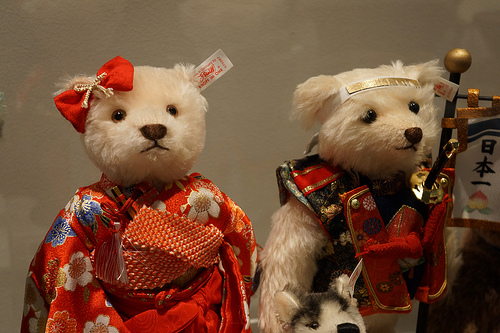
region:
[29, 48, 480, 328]
two teddy bears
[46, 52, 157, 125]
a red bow on the bears ear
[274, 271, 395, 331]
a toy wolf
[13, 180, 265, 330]
a red kimono dress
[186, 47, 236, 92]
the tag on the bears ear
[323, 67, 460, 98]
a headband on the "male" bear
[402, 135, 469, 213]
a pretend sword prop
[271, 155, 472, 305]
samurai gear on one of the bears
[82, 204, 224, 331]
sashes on the "female" bear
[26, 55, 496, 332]
cute teddies dressed in chinese costumes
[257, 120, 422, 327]
the teddy bear in red cloth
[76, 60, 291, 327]
the teddy bear in red cloth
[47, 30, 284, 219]
the teddy bear in red cloth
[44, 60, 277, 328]
dressed up teddy bear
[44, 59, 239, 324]
teddy bear wearing kimono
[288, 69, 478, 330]
teddy bear dressed up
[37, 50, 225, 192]
red bow on teddy bear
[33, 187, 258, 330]
red kimono with white flowers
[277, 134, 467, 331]
black, gold, and red vest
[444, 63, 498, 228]
banner on black pole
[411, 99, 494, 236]
brown, black, red, yellow banner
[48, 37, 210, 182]
white teddy bear with black nose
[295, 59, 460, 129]
gold and white headband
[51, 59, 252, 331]
teddy bear wearing costume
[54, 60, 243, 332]
tan stuffed teddy bear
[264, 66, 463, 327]
stuffed dog in costume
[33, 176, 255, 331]
red floral doll kimono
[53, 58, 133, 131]
red bow on teddy bear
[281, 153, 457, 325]
japanese fighter doll outfit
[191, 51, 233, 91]
red and white tag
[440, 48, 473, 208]
black and gold sign holder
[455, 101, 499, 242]
wooden sign on pole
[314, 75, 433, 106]
white and gold headband